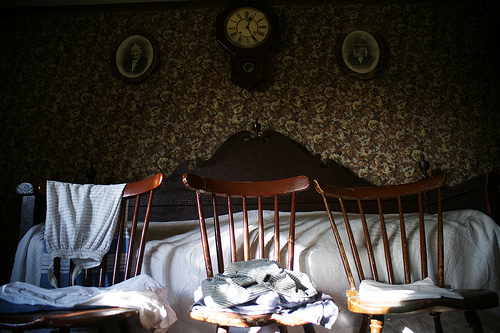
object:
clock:
[216, 5, 273, 53]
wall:
[0, 1, 499, 285]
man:
[345, 35, 374, 68]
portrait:
[332, 23, 388, 81]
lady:
[120, 39, 151, 76]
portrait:
[111, 32, 158, 84]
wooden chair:
[310, 178, 499, 332]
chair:
[182, 174, 338, 333]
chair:
[0, 175, 165, 332]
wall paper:
[0, 0, 498, 188]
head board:
[16, 122, 500, 241]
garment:
[40, 181, 128, 289]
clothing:
[0, 273, 177, 332]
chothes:
[198, 258, 318, 310]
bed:
[13, 121, 500, 333]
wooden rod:
[210, 196, 227, 273]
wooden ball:
[248, 122, 262, 132]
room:
[0, 0, 499, 332]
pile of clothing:
[190, 258, 338, 331]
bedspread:
[6, 208, 498, 332]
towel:
[357, 277, 465, 302]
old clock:
[218, 7, 280, 93]